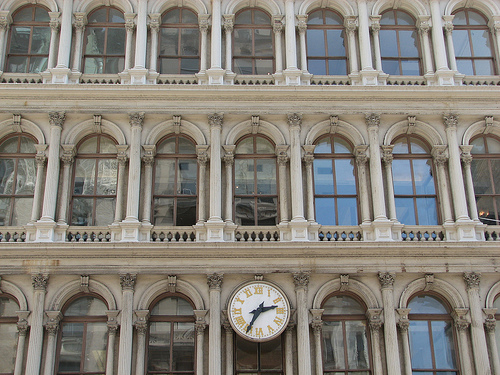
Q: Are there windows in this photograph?
A: Yes, there are windows.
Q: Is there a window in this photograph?
A: Yes, there are windows.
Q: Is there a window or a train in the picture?
A: Yes, there are windows.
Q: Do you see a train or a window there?
A: Yes, there are windows.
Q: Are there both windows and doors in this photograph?
A: No, there are windows but no doors.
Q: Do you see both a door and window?
A: No, there are windows but no doors.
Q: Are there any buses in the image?
A: No, there are no buses.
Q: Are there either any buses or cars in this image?
A: No, there are no buses or cars.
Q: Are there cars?
A: No, there are no cars.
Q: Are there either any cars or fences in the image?
A: No, there are no cars or fences.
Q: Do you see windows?
A: Yes, there are windows.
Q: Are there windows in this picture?
A: Yes, there are windows.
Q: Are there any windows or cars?
A: Yes, there are windows.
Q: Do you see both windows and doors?
A: No, there are windows but no doors.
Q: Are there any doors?
A: No, there are no doors.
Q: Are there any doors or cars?
A: No, there are no doors or cars.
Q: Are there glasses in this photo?
A: No, there are no glasses.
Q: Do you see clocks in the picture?
A: Yes, there is a clock.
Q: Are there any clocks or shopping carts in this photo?
A: Yes, there is a clock.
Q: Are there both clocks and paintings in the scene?
A: No, there is a clock but no paintings.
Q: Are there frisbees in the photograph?
A: No, there are no frisbees.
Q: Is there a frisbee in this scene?
A: No, there are no frisbees.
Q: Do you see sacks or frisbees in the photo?
A: No, there are no frisbees or sacks.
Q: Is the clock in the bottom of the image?
A: Yes, the clock is in the bottom of the image.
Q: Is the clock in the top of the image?
A: No, the clock is in the bottom of the image.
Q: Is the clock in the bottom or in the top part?
A: The clock is in the bottom of the image.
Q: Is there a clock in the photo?
A: Yes, there is a clock.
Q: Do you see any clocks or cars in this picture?
A: Yes, there is a clock.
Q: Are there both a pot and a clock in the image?
A: No, there is a clock but no pots.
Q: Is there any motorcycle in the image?
A: No, there are no motorcycles.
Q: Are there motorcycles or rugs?
A: No, there are no motorcycles or rugs.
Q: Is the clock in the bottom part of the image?
A: Yes, the clock is in the bottom of the image.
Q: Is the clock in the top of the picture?
A: No, the clock is in the bottom of the image.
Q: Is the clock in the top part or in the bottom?
A: The clock is in the bottom of the image.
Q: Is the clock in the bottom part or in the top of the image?
A: The clock is in the bottom of the image.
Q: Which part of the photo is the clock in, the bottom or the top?
A: The clock is in the bottom of the image.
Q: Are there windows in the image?
A: Yes, there are windows.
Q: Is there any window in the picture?
A: Yes, there are windows.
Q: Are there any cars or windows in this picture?
A: Yes, there are windows.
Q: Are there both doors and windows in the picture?
A: No, there are windows but no doors.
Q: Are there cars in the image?
A: No, there are no cars.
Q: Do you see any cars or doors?
A: No, there are no cars or doors.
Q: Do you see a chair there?
A: No, there are no chairs.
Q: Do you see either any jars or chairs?
A: No, there are no chairs or jars.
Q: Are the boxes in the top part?
A: Yes, the boxes are in the top of the image.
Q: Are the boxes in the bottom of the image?
A: No, the boxes are in the top of the image.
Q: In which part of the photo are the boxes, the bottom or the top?
A: The boxes are in the top of the image.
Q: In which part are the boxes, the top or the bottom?
A: The boxes are in the top of the image.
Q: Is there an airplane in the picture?
A: No, there are no airplanes.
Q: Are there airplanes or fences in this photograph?
A: No, there are no airplanes or fences.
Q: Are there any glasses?
A: No, there are no glasses.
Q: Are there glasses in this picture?
A: No, there are no glasses.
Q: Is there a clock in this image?
A: Yes, there is a clock.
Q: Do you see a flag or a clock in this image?
A: Yes, there is a clock.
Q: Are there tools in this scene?
A: No, there are no tools.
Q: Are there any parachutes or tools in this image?
A: No, there are no tools or parachutes.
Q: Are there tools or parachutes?
A: No, there are no tools or parachutes.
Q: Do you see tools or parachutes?
A: No, there are no tools or parachutes.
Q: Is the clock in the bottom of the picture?
A: Yes, the clock is in the bottom of the image.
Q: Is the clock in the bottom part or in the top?
A: The clock is in the bottom of the image.